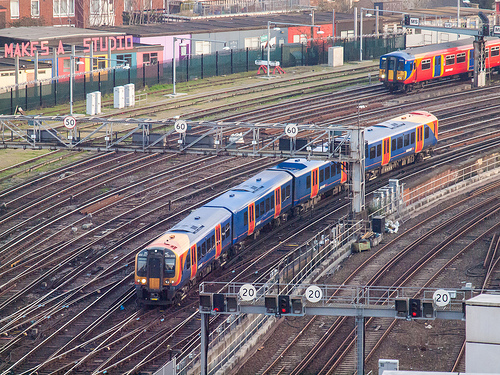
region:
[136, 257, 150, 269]
window of a train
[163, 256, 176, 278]
window of a train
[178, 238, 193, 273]
window of a train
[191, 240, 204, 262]
window of a train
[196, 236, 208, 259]
window of a train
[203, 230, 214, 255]
window of a train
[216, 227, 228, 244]
window of a train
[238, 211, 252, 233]
window of a train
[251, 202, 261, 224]
window of a train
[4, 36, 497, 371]
two trains on tracks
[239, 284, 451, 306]
round signs with numbers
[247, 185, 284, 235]
orange dors on train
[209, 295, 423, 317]
three glowing red lights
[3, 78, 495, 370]
rows of multiple train tracks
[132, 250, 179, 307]
front of passenger train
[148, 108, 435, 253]
roof of passenger train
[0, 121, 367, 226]
metal frame over tracks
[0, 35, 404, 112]
metal fence with posts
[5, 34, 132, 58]
red letters of sign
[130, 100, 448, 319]
Train has 4 cars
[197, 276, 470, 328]
Light are red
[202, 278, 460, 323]
Speed limit is 20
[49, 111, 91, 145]
Speed limit is 50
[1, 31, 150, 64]
Sign says makes a studio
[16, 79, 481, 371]
Lots of train tracks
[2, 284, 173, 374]
Train tracks are crossing each other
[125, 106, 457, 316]
Train color is blue with red and yellow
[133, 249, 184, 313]
Train headlights are on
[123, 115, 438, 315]
a blue and red train on a track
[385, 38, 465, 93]
a red and blue train on a train track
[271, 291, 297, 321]
a train signal over a train track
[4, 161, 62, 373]
several sets sets of train tracks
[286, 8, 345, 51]
a red building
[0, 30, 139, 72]
large red letters on top of a building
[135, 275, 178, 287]
a head light out on the front of a train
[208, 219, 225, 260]
a red door on a train car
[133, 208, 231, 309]
an orange and blue train engine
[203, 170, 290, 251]
a blue and orange passenger car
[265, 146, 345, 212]
a blue and orange passenger car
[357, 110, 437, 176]
a blue and orange passenger car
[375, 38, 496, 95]
a red orange and blue train engine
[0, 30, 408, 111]
a long green fence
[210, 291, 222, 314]
an electronic train signal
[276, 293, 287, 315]
an electronic train signal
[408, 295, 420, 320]
an electronic train signal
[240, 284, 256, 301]
white round 20 sign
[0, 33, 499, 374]
The train is on the tracks.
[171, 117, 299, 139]
The number 60 is on the sign.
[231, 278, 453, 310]
The number 20 is on the sign.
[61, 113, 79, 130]
The number 50 is on the sign.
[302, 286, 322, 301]
number 20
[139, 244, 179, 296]
a train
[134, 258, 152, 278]
windshield on the train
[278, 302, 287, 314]
a red light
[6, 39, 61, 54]
letters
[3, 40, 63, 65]
letters are red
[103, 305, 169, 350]
a train track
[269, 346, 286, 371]
the train tracks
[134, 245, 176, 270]
windshield of the train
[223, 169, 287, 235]
car of the train